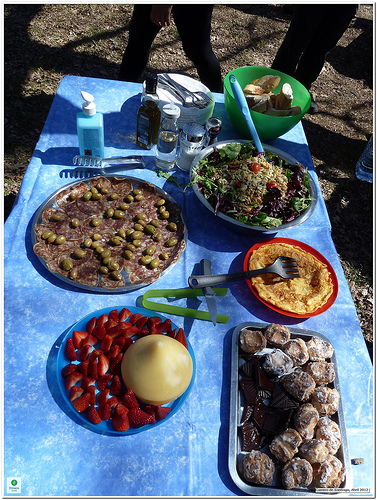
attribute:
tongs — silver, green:
[137, 267, 238, 330]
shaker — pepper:
[207, 117, 226, 147]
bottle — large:
[190, 93, 204, 165]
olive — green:
[265, 188, 284, 212]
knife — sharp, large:
[230, 82, 265, 154]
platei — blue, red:
[240, 236, 348, 321]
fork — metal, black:
[194, 257, 322, 295]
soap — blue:
[69, 89, 110, 157]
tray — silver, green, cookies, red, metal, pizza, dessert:
[236, 320, 345, 487]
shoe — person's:
[344, 140, 373, 181]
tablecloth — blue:
[24, 72, 369, 487]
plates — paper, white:
[158, 76, 209, 117]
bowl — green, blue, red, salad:
[197, 150, 317, 229]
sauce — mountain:
[127, 331, 193, 392]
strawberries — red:
[69, 325, 132, 421]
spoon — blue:
[227, 82, 291, 163]